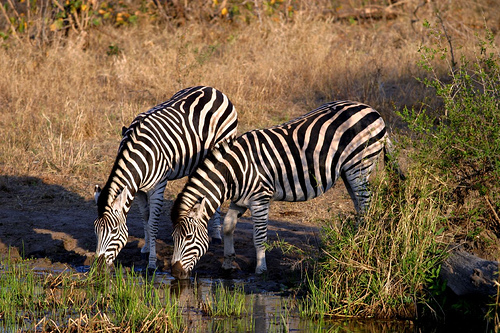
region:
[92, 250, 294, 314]
on a sunny day, even mud reflects drinking zebras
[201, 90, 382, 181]
thin rust stripes amid b/w stripes on both zebras butt ends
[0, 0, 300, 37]
yellowing leaves amid dry grass in background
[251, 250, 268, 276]
on the ankle, zebra has no stripes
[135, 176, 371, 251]
thinner, small stripes on zebras' legs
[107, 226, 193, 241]
zebras' eyes are ringed in black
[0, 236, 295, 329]
grass grows tall in muddy water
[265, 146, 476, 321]
large clump of swamp grass, almost zebra high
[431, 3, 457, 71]
leafless branch grows skyward from bush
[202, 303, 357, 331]
reflections of long green grass in water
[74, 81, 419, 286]
Two zebras drinking in the meadow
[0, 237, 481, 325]
Green grass close to water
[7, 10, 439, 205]
Dry vegetation behind zebras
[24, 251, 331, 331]
Creek in the meadow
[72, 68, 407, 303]
Zebras with neck down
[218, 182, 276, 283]
Front legs of zebra are in the water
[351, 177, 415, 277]
Back legs of zebra are on ground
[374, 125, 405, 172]
Tail of giraffe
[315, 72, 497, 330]
Grass and weeds are high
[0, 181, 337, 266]
Shadows of zebras casting in the ground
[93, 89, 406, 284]
Two zebras, drinking.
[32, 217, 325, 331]
Small, boggy water hole with zebra heads drinking.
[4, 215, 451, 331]
Marshy, green grass and brown, dried out stalks, surrounding water hole.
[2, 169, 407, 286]
Shadow of zebras, caused by bright sunlight.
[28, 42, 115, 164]
Dried out, brown stalks of vegetation.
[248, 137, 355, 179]
Tan, black and white stripes on zebra.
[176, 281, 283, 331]
Reflection of zebra head, drinking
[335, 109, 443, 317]
Back legs of zebra, obscured by tall stalks of dry and fresh grass.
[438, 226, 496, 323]
Dried husk of tree trunk, semi-covered by grass.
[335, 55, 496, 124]
Shadowed area on dried out grass.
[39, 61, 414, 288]
two zebras drinking water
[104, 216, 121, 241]
zebras left eye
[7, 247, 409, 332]
small body of water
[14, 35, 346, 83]
brown dry vegetation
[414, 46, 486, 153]
green sparse shrubery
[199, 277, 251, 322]
a patch of green grass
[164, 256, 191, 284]
a zebras brown nose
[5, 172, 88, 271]
shadow given off by zebra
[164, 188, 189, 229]
front of a zebras mane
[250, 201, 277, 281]
left front leg of a zebra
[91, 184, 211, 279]
two zebra heads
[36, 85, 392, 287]
zebras taking drink of water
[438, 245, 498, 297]
dead log in field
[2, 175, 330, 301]
shadows on ground from zebras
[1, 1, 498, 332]
dry, brown, grassy field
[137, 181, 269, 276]
4 zebra front legs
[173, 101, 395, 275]
black and white zebra on right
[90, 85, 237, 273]
black and white zebra on left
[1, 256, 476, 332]
shallow standing water on ground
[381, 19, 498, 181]
thin branches of green bush